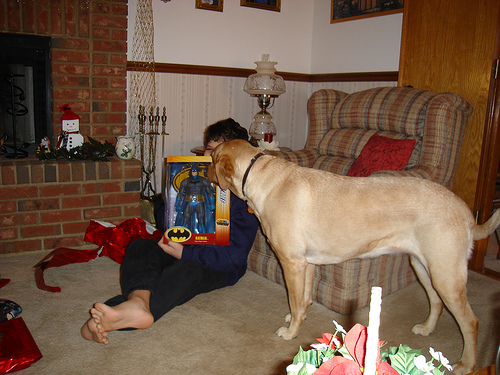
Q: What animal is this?
A: Dog.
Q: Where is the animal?
A: On the floor.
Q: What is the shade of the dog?
A: Blonde.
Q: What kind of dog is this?
A: Lab.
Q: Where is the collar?
A: On the dog's neck.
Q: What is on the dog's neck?
A: Collar.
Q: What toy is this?
A: Batman.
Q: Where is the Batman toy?
A: On the boy's lap.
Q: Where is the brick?
A: On the fireplace.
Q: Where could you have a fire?
A: In the fireplace.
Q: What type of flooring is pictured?
A: Carpet.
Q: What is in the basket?
A: Flowers.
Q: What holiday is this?
A: Christmas.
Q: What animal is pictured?
A: Dog.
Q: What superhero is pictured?
A: Batman.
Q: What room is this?
A: Living room.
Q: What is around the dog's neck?
A: Collar.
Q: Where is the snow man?
A: Next to the fireplace.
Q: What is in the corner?
A: Lamp.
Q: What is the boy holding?
A: A batman toy.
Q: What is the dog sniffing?
A: A batman toy?.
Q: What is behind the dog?
A: A chair.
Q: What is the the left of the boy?
A: A fireplace.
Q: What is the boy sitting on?
A: The floor.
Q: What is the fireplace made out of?
A: Brick.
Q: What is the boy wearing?
A: Sweatpants and a sweatshirt.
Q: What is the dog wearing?
A: A collar.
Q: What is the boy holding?
A: A batman toy.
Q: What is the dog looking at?
A: The boy holding the batman action figure.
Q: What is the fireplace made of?
A: Brick.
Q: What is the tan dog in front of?
A: The chair.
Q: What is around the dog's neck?
A: A black collar.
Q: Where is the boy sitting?
A: On the floor.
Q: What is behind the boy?
A: Red gift wrap.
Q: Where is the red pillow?
A: On the chair.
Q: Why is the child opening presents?
A: It is christmas.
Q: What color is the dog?
A: Yellow.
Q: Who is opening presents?
A: The child.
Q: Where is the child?
A: In the living room.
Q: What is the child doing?
A: Opening presents.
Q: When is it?
A: Christmas.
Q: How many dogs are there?
A: 1.